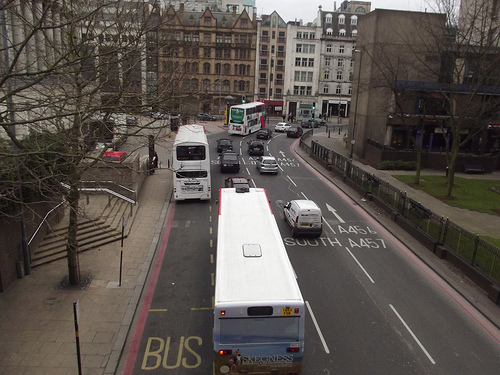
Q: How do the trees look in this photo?
A: Bare.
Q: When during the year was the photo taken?
A: In autumn.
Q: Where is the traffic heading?
A: South.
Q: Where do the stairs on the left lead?
A: To a building.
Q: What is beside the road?
A: Fence.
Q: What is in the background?
A: Building.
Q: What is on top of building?
A: Gables.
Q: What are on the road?
A: Buses.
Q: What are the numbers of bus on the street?
A: Three.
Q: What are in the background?
A: Buildings.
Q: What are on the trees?
A: No leaves.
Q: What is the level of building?
A: Multi-story.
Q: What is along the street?
A: Fence.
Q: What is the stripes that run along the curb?
A: Red strip.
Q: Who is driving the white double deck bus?
A: Bus driver.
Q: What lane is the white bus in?
A: Bus.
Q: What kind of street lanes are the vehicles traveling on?
A: One-Way.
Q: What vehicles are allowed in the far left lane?
A: Transit buses.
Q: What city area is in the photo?
A: Downtown.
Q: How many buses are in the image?
A: 3.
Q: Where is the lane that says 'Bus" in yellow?
A: On the left.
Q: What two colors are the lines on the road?
A: White and yellow.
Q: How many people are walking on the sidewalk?
A: 0.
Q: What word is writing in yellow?
A: Bus.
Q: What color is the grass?
A: Green.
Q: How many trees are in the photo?
A: 3.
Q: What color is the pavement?
A: Black.